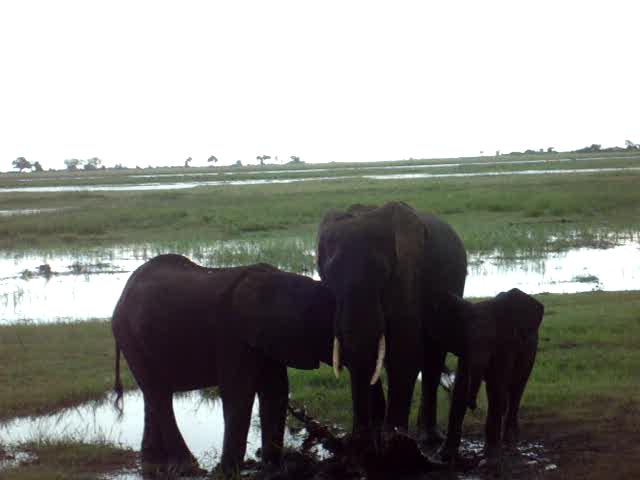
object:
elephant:
[316, 200, 470, 451]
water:
[2, 241, 638, 322]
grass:
[0, 153, 637, 478]